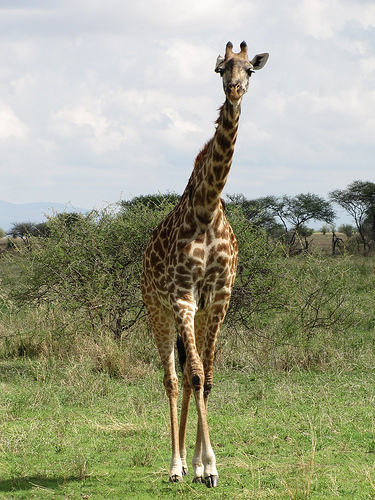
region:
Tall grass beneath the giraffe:
[28, 384, 161, 469]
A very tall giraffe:
[138, 27, 268, 483]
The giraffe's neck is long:
[177, 93, 255, 230]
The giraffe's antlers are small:
[222, 36, 247, 60]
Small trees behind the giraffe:
[44, 218, 139, 331]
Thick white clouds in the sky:
[33, 36, 178, 157]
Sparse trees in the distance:
[257, 189, 373, 250]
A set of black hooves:
[167, 471, 218, 486]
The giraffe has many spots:
[148, 199, 233, 344]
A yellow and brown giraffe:
[133, 19, 273, 483]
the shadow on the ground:
[0, 475, 92, 494]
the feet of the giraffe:
[166, 460, 220, 487]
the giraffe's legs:
[147, 304, 223, 488]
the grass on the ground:
[240, 387, 362, 496]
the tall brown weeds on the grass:
[266, 426, 319, 498]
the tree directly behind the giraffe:
[43, 205, 284, 344]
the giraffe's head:
[214, 41, 267, 99]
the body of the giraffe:
[141, 203, 235, 313]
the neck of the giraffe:
[188, 97, 246, 204]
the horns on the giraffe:
[223, 39, 248, 55]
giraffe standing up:
[113, 36, 306, 489]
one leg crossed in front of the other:
[179, 336, 228, 489]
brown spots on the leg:
[174, 305, 202, 361]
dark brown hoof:
[204, 472, 221, 488]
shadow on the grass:
[4, 459, 94, 495]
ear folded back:
[209, 51, 227, 74]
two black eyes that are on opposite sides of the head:
[214, 66, 258, 76]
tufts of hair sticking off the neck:
[210, 104, 222, 125]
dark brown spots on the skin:
[147, 232, 191, 295]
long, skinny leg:
[179, 309, 225, 497]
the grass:
[251, 396, 298, 498]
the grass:
[267, 453, 286, 498]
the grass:
[262, 405, 273, 489]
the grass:
[258, 439, 274, 495]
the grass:
[259, 468, 270, 496]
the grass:
[251, 386, 275, 483]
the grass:
[238, 424, 277, 494]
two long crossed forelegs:
[165, 283, 234, 493]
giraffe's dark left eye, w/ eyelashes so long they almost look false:
[244, 63, 257, 77]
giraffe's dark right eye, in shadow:
[217, 65, 226, 77]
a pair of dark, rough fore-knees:
[186, 369, 214, 400]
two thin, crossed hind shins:
[161, 388, 188, 461]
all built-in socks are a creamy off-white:
[161, 444, 228, 476]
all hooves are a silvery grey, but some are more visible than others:
[155, 464, 235, 494]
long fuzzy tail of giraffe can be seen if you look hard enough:
[175, 331, 188, 372]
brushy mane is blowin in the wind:
[181, 98, 227, 174]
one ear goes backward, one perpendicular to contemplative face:
[209, 48, 273, 79]